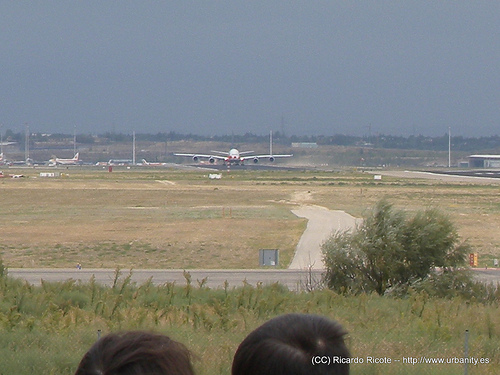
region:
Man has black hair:
[229, 311, 309, 365]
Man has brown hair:
[78, 336, 190, 366]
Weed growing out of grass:
[82, 273, 169, 314]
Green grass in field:
[199, 336, 228, 366]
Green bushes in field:
[308, 206, 460, 289]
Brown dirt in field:
[41, 216, 143, 241]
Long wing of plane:
[166, 149, 214, 158]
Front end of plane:
[226, 150, 246, 165]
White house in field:
[464, 144, 498, 172]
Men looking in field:
[62, 315, 357, 374]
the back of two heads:
[66, 278, 364, 371]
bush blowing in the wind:
[320, 186, 462, 283]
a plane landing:
[167, 123, 309, 186]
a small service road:
[288, 175, 364, 265]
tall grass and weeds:
[22, 263, 348, 324]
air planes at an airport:
[14, 123, 130, 175]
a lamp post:
[432, 117, 467, 170]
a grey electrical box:
[257, 243, 283, 269]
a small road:
[31, 258, 322, 286]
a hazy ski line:
[34, 23, 429, 145]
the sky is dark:
[94, 26, 474, 116]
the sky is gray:
[107, 32, 449, 112]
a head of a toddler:
[232, 309, 372, 366]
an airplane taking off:
[167, 137, 292, 173]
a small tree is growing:
[314, 200, 466, 299]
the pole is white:
[439, 125, 465, 169]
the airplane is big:
[175, 140, 292, 172]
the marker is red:
[465, 250, 474, 264]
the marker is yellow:
[474, 252, 481, 267]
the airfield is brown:
[52, 180, 201, 252]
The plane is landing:
[171, 143, 309, 189]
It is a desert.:
[17, 13, 495, 321]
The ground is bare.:
[60, 172, 283, 249]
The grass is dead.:
[56, 193, 241, 248]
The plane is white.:
[143, 106, 318, 196]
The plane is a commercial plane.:
[170, 129, 306, 191]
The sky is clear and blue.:
[54, 15, 439, 92]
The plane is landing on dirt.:
[140, 132, 411, 307]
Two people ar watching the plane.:
[58, 317, 364, 374]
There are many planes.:
[15, 131, 456, 202]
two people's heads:
[55, 290, 360, 372]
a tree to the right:
[311, 183, 479, 302]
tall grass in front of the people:
[18, 270, 93, 330]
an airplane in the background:
[164, 123, 318, 188]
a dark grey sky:
[50, 17, 176, 109]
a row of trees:
[297, 85, 412, 181]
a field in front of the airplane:
[35, 188, 116, 263]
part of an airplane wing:
[241, 137, 306, 177]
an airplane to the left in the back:
[31, 137, 98, 185]